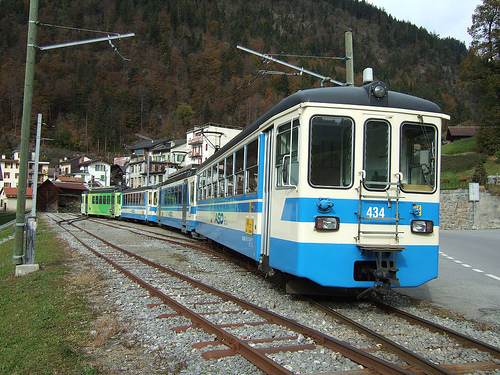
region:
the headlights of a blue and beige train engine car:
[315, 215, 339, 232]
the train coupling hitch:
[354, 262, 398, 292]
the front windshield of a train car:
[306, 112, 436, 194]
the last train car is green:
[80, 187, 120, 213]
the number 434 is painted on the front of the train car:
[365, 204, 385, 220]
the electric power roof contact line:
[197, 127, 227, 149]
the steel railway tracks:
[44, 209, 498, 373]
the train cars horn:
[366, 80, 389, 102]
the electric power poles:
[14, 0, 133, 270]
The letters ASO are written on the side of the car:
[197, 210, 262, 232]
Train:
[80, 70, 447, 300]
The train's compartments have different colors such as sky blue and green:
[50, 70, 450, 301]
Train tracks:
[43, 213, 494, 370]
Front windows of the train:
[311, 116, 436, 191]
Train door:
[257, 130, 277, 266]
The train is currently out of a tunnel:
[55, 65, 450, 306]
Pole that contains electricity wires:
[11, 0, 134, 271]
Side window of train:
[273, 123, 296, 184]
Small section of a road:
[440, 223, 496, 310]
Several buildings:
[2, 125, 239, 210]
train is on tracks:
[43, 81, 499, 373]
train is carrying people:
[80, 84, 440, 294]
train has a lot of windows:
[80, 88, 442, 289]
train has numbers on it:
[365, 206, 386, 218]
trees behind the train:
[8, 26, 495, 143]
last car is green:
[80, 186, 123, 218]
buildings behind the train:
[1, 121, 240, 197]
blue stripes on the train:
[121, 189, 470, 291]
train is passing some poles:
[15, 25, 139, 283]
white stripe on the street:
[437, 246, 499, 291]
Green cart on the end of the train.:
[66, 178, 127, 230]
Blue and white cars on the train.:
[122, 82, 457, 323]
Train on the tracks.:
[75, 78, 459, 333]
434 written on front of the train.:
[347, 196, 413, 235]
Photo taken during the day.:
[1, 0, 493, 372]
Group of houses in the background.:
[0, 102, 253, 197]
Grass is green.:
[4, 209, 91, 374]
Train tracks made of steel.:
[55, 192, 497, 370]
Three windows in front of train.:
[306, 109, 446, 208]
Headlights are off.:
[306, 203, 441, 254]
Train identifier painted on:
[357, 202, 389, 222]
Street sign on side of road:
[466, 182, 479, 222]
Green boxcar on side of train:
[82, 188, 114, 217]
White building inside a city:
[80, 159, 112, 189]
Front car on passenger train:
[192, 87, 442, 307]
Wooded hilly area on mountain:
[89, 45, 257, 127]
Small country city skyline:
[62, 130, 239, 185]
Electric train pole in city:
[16, 0, 135, 272]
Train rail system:
[59, 217, 285, 373]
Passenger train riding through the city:
[82, 93, 449, 295]